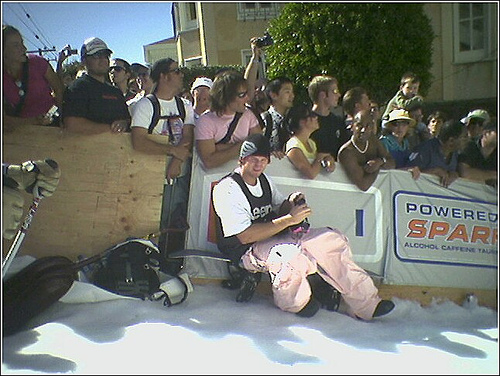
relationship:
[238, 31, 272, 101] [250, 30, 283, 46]
arm holding camera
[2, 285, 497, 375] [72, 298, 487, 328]
snow covers ground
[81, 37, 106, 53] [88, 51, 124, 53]
hat with brim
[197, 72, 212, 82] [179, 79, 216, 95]
hat with brim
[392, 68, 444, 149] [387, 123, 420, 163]
boy sitting on man's shoulders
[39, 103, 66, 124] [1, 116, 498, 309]
camera over wall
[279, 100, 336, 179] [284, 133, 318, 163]
person wearing shirt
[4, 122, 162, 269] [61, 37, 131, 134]
board in front of man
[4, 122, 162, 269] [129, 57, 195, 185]
board in front of people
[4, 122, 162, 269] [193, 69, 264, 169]
board in front of people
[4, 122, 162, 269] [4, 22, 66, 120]
board in front of person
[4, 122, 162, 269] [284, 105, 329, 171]
board in front of person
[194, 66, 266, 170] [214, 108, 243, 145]
man with strap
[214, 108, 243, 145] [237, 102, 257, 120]
strap across shoulder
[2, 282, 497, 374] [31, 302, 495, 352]
shadow on ground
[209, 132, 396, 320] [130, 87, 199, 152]
man wearing shirt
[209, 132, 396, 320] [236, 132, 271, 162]
man wearing hat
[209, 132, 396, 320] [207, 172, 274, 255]
man wearing vest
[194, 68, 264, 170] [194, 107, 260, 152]
man wearing pink shirt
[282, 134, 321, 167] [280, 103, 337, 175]
shirt on woman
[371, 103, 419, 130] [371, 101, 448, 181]
hat on woman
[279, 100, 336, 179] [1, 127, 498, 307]
person behind blockade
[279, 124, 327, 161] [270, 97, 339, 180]
shirt on woman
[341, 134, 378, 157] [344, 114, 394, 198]
white necklace on man